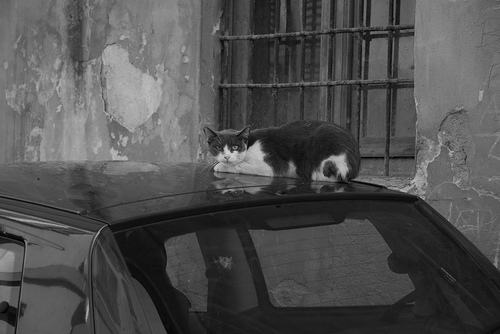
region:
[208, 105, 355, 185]
a black and white cat standing on a car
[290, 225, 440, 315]
a car back windshield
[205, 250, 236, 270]
some dammaged glass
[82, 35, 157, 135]
a dammaged wall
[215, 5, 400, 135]
a house window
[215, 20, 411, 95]
some bars on the window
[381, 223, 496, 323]
a car windshield wiper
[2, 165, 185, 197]
the roof of a black car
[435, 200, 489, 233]
some scratchings on the damaged wall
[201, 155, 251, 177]
some white cat wiskers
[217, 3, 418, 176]
metal bars on window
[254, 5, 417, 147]
reflection on window surface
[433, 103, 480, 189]
piece of missing wall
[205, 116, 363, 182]
body of reclined cat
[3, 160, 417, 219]
roof on top of car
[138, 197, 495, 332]
windshield on front of car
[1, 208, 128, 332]
reflection on car paint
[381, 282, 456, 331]
steering wheel on dashboard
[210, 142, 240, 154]
eyes looking at camera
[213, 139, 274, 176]
white fur on cat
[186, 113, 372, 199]
A cat is sitting on top of the car.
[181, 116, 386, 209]
The cat is black and white.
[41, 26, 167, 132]
The paint is peeling off the building.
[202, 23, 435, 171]
Bars on the window.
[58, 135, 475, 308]
The car is parked next to the building.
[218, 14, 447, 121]
The window is on the building.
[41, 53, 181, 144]
The building have marks on it.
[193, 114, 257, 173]
The cat ears are sticking up.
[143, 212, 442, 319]
The glass on the back window of the car.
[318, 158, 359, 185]
The cat has a black tail.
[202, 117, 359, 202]
cat on top of a car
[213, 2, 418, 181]
metal bars on a window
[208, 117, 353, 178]
black and white cat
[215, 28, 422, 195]
window in a concrete wall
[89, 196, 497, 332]
rear windshield of a car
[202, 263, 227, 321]
seat belt hanging inside a car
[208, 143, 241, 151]
light colored eyes of a cat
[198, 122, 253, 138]
pointy ears of a cat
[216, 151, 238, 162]
white nose of a cat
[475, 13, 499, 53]
letter "B" etched into a concrete wall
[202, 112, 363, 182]
a cat on a car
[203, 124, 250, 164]
head of a cat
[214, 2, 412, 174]
bars over a window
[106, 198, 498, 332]
rear window in a car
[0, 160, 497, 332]
the top of a small car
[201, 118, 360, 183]
a bicolored cat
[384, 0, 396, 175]
a rusted metal pole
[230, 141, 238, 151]
the eye of a cat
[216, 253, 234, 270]
a white mark on a window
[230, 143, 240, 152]
eye of a cat